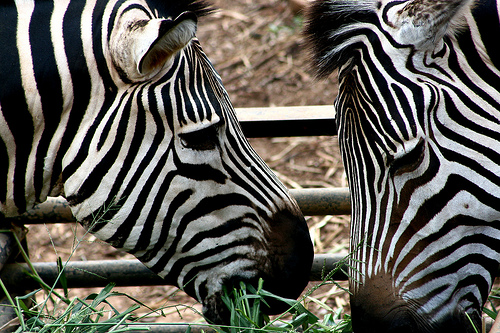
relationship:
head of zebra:
[64, 2, 314, 317] [1, 3, 314, 332]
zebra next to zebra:
[1, 3, 314, 332] [312, 0, 498, 333]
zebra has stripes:
[1, 3, 314, 332] [8, 51, 123, 151]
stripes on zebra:
[8, 51, 123, 151] [1, 3, 314, 332]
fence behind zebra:
[10, 97, 376, 307] [1, 3, 314, 332]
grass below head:
[18, 286, 345, 332] [64, 2, 314, 317]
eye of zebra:
[186, 129, 221, 148] [1, 3, 314, 332]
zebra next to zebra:
[312, 0, 498, 333] [1, 3, 314, 332]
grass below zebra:
[18, 286, 345, 332] [1, 3, 314, 332]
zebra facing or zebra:
[312, 0, 498, 333] [1, 3, 314, 332]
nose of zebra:
[277, 220, 315, 291] [1, 3, 314, 332]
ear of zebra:
[119, 10, 196, 79] [1, 3, 314, 332]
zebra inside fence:
[1, 3, 314, 332] [10, 97, 376, 307]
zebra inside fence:
[312, 0, 498, 333] [10, 97, 376, 307]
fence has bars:
[10, 97, 376, 307] [285, 183, 354, 235]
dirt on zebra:
[254, 215, 282, 254] [1, 3, 314, 332]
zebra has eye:
[1, 3, 314, 332] [186, 129, 221, 148]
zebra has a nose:
[1, 3, 314, 332] [277, 220, 315, 291]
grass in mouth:
[18, 286, 345, 332] [204, 271, 295, 322]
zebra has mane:
[312, 0, 498, 333] [308, 6, 371, 59]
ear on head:
[119, 10, 196, 79] [64, 2, 314, 317]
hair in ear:
[166, 28, 183, 54] [119, 10, 196, 79]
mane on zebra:
[308, 6, 371, 59] [312, 0, 498, 333]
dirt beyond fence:
[230, 33, 315, 109] [10, 97, 376, 307]